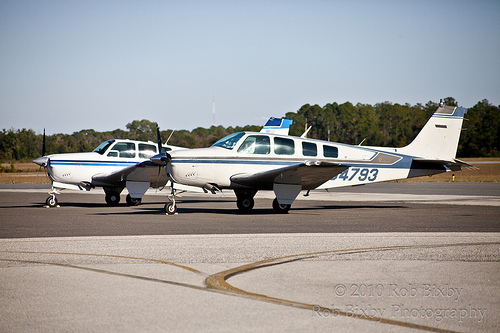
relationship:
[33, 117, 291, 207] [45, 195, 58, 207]
airplane has front tire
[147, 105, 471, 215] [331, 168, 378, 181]
plane has number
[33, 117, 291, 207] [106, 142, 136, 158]
airplane has window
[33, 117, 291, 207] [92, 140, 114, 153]
airplane has windshield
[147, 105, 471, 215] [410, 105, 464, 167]
plane has tail wing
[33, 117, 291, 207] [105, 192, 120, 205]
airplane has tire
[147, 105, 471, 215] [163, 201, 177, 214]
plane has wheel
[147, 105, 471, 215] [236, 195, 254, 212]
plane has back wheel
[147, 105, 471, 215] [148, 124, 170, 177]
plane has propeller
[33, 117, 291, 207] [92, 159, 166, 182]
airplane has wing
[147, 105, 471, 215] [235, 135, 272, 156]
plane has window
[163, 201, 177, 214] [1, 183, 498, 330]
wheel on top of ground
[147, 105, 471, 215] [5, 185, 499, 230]
plane on a landing lane